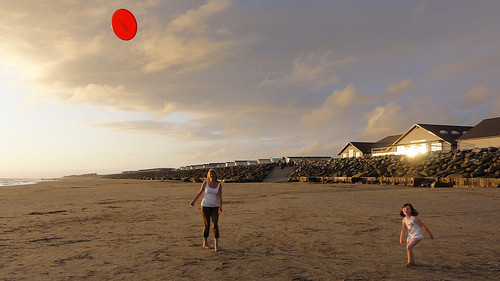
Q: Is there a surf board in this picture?
A: No, there are no surfboards.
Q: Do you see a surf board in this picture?
A: No, there are no surfboards.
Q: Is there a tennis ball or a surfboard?
A: No, there are no surfboards or tennis balls.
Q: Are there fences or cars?
A: No, there are no cars or fences.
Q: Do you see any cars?
A: No, there are no cars.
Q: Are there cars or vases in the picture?
A: No, there are no cars or vases.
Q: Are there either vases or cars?
A: No, there are no cars or vases.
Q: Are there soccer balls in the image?
A: No, there are no soccer balls.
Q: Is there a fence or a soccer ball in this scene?
A: No, there are no soccer balls or fences.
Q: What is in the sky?
A: The clouds are in the sky.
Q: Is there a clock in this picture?
A: No, there are no clocks.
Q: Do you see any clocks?
A: No, there are no clocks.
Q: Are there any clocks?
A: No, there are no clocks.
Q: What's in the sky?
A: The clouds are in the sky.